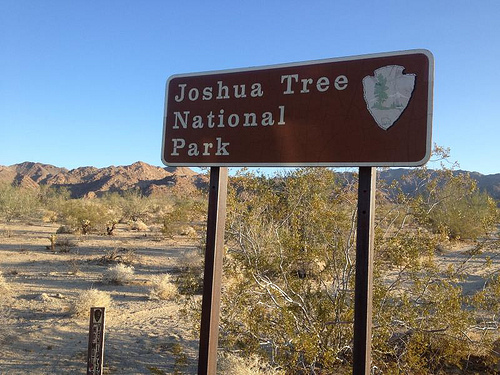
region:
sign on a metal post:
[159, 42, 436, 373]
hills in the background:
[2, 102, 207, 238]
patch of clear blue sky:
[8, 7, 160, 143]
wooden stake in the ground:
[78, 287, 119, 374]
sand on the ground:
[3, 212, 202, 297]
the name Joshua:
[161, 67, 264, 106]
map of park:
[358, 62, 433, 141]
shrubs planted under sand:
[2, 172, 202, 314]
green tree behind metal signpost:
[160, 57, 487, 372]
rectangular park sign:
[152, 43, 455, 175]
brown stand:
[178, 197, 283, 374]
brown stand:
[174, 228, 242, 333]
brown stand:
[178, 202, 248, 297]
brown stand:
[195, 252, 267, 360]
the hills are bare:
[29, 160, 174, 194]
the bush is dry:
[274, 206, 451, 367]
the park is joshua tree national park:
[4, 131, 496, 366]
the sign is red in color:
[171, 77, 445, 169]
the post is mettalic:
[197, 190, 232, 373]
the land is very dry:
[26, 200, 196, 370]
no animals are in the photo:
[11, 150, 496, 370]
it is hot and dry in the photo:
[5, 4, 498, 349]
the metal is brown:
[201, 199, 235, 371]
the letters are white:
[166, 86, 343, 151]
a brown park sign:
[158, 56, 435, 180]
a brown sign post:
[185, 165, 231, 372]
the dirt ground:
[0, 214, 498, 369]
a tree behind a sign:
[199, 167, 480, 369]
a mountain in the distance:
[12, 154, 191, 201]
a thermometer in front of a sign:
[84, 306, 109, 370]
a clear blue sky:
[2, 2, 498, 166]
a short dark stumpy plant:
[102, 248, 133, 261]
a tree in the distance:
[65, 199, 103, 228]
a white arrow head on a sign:
[360, 63, 418, 133]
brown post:
[148, 200, 285, 345]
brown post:
[164, 242, 251, 367]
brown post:
[195, 235, 293, 363]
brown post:
[168, 232, 240, 314]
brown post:
[192, 242, 257, 327]